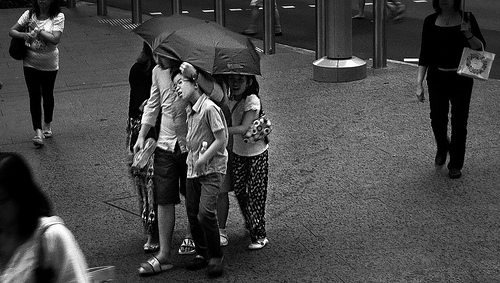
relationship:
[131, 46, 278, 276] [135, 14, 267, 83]
people under umbrella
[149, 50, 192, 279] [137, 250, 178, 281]
man wearing sandal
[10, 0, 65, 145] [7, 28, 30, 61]
girl carrying purse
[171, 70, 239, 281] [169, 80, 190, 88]
boy wearing glasses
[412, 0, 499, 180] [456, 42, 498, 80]
woman carrying paper bag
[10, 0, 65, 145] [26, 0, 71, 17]
girl has hair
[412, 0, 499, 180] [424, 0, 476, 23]
woman has hair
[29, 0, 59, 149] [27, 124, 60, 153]
girl wearing shoe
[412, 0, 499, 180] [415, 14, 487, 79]
woman wearing shirt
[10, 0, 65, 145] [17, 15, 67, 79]
girl wearing shirt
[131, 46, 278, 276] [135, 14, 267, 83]
group under umbrella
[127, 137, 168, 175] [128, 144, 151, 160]
bottle for drinking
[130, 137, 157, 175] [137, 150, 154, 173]
bottle has water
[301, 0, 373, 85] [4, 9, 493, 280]
pylon on sidewalk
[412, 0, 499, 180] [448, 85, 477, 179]
person has leg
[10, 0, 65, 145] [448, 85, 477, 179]
girl has leg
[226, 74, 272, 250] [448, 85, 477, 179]
people has leg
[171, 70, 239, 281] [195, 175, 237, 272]
person has leg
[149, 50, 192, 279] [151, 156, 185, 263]
person has leg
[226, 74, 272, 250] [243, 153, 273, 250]
people has leg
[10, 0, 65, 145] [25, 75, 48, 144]
girl has leg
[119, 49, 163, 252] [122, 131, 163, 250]
person has leg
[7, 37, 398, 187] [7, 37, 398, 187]
floor of floor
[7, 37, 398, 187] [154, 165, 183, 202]
floor of trouser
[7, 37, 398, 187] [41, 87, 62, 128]
floor of trouser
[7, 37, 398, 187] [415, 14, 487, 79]
floor of shirt